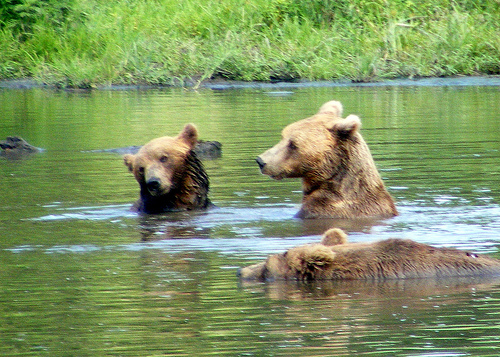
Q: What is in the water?
A: Bears.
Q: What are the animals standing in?
A: Water.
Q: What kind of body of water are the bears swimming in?
A: A lake.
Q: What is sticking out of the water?
A: Bear heads.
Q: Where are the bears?
A: In the water.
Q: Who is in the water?
A: Bears.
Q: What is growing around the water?
A: Grass.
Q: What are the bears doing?
A: Playing in water.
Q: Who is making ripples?
A: Bears.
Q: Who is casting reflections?
A: Bears.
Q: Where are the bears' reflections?
A: In the water.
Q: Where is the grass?
A: On the bank.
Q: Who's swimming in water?
A: Bears.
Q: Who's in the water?
A: Brown bears.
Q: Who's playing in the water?
A: Three bears.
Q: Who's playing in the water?
A: A brown bear.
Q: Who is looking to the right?
A: A large brown bear.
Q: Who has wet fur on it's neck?
A: A brown bear.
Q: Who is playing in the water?
A: A brown bear.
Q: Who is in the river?
A: Three bears.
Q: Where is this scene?
A: Watering hole.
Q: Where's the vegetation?
A: Background.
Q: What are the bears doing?
A: Bathing.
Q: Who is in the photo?
A: Nobody.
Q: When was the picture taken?
A: Daytime.